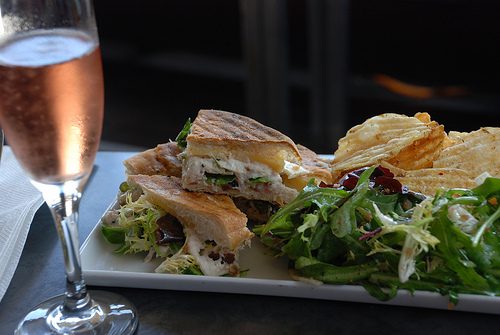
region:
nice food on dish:
[123, 51, 471, 311]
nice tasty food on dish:
[75, 95, 491, 301]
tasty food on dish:
[89, 94, 481, 316]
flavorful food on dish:
[91, 100, 475, 300]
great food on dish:
[84, 91, 487, 313]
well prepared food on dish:
[93, 97, 483, 312]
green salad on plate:
[273, 184, 465, 289]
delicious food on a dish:
[90, 97, 493, 311]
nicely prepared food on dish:
[110, 85, 490, 309]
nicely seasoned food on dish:
[124, 95, 487, 307]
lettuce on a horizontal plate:
[312, 192, 424, 263]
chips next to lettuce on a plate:
[342, 115, 429, 165]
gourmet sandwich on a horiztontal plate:
[182, 110, 301, 205]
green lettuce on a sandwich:
[117, 204, 154, 250]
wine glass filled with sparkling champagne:
[0, 1, 136, 333]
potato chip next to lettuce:
[380, 159, 473, 195]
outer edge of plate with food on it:
[105, 272, 246, 291]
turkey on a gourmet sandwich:
[190, 159, 273, 181]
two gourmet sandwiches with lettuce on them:
[102, 110, 300, 275]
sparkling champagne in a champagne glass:
[0, 32, 100, 184]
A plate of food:
[96, 42, 489, 287]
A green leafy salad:
[267, 184, 492, 271]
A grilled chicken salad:
[182, 92, 310, 208]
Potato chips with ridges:
[331, 109, 432, 175]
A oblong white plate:
[83, 221, 359, 308]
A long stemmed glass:
[1, 46, 139, 334]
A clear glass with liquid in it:
[1, 14, 129, 334]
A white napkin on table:
[0, 182, 33, 259]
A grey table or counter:
[156, 302, 248, 334]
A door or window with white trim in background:
[181, 7, 367, 110]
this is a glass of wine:
[0, 0, 139, 333]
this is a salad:
[251, 186, 498, 303]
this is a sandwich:
[100, 105, 325, 276]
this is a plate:
[65, 153, 498, 318]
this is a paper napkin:
[2, 138, 70, 312]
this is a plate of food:
[66, 105, 496, 311]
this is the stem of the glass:
[30, 180, 104, 299]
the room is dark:
[100, 0, 496, 152]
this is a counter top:
[0, 148, 497, 330]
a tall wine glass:
[1, 0, 141, 331]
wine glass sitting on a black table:
[4, 1, 141, 334]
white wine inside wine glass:
[4, 27, 109, 186]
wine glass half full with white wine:
[3, 1, 148, 333]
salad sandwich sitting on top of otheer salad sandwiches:
[184, 101, 296, 206]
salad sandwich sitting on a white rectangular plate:
[113, 160, 253, 275]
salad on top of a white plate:
[274, 172, 498, 305]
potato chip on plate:
[320, 111, 429, 174]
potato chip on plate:
[383, 156, 476, 200]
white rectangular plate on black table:
[79, 141, 497, 312]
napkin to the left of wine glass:
[3, 147, 45, 324]